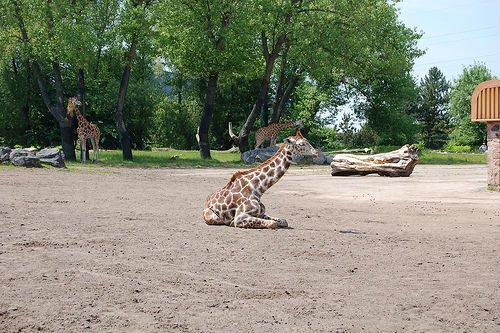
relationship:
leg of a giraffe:
[232, 200, 280, 228] [200, 122, 320, 229]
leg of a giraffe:
[261, 211, 289, 226] [200, 122, 320, 229]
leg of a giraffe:
[232, 212, 279, 230] [253, 118, 293, 154]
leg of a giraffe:
[265, 134, 278, 153] [251, 110, 295, 154]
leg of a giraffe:
[232, 212, 279, 230] [63, 93, 101, 161]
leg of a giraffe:
[232, 212, 279, 230] [64, 99, 102, 161]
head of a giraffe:
[64, 92, 82, 116] [63, 93, 103, 165]